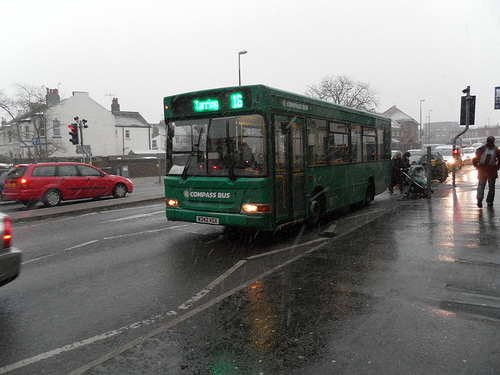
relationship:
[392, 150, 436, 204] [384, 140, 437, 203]
people are off bus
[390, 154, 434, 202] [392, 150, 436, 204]
stroller being pushed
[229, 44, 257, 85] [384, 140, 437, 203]
light pole behind bus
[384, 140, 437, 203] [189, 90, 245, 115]
bus light is green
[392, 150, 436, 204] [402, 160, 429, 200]
person pushing stroller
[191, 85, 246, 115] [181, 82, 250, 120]
sign on bus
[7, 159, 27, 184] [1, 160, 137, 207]
lights on station wagon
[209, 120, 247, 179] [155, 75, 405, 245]
wiper on bus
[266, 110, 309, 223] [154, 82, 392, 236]
door on bus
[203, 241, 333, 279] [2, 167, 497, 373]
line on road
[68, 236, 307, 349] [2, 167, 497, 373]
rain on road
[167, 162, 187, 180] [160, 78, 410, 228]
sign on front bus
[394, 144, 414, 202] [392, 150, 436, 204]
woman pushing carriage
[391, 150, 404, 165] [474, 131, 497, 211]
cap on man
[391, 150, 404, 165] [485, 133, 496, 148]
cap on head